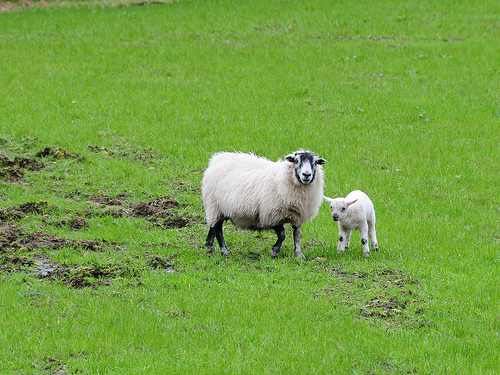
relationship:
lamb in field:
[200, 147, 328, 261] [0, 2, 498, 372]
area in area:
[5, 195, 178, 271] [0, 0, 500, 375]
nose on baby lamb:
[333, 212, 338, 225] [322, 186, 384, 263]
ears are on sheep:
[286, 155, 326, 162] [202, 149, 324, 254]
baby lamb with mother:
[320, 187, 387, 258] [196, 134, 326, 266]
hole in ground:
[0, 146, 205, 375] [1, 0, 498, 373]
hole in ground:
[0, 146, 191, 289] [1, 0, 498, 373]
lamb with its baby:
[200, 147, 328, 261] [324, 179, 387, 253]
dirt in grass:
[2, 142, 179, 295] [3, 2, 496, 373]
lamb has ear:
[200, 147, 328, 261] [280, 147, 303, 172]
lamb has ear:
[200, 147, 328, 261] [314, 188, 331, 210]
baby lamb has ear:
[323, 190, 379, 258] [306, 148, 331, 175]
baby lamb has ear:
[323, 190, 379, 258] [280, 147, 303, 172]